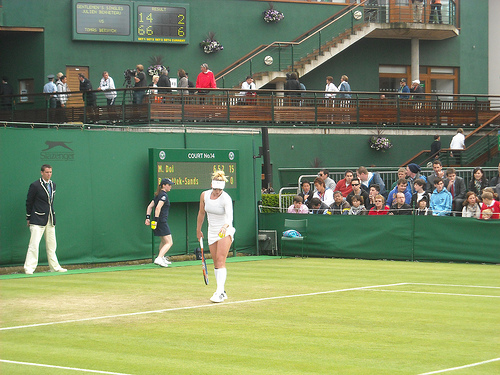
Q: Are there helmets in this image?
A: No, there are no helmets.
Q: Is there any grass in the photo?
A: Yes, there is grass.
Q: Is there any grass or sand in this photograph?
A: Yes, there is grass.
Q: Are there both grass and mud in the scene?
A: No, there is grass but no mud.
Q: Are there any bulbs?
A: No, there are no bulbs.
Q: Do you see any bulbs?
A: No, there are no bulbs.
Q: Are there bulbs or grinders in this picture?
A: No, there are no bulbs or grinders.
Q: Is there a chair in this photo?
A: No, there are no chairs.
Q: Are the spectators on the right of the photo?
A: Yes, the spectators are on the right of the image.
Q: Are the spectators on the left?
A: No, the spectators are on the right of the image.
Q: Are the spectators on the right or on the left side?
A: The spectators are on the right of the image.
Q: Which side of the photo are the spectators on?
A: The spectators are on the right of the image.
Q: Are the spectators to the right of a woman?
A: Yes, the spectators are to the right of a woman.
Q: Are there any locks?
A: No, there are no locks.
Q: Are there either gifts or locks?
A: No, there are no locks or gifts.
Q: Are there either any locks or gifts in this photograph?
A: No, there are no locks or gifts.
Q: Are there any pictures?
A: No, there are no pictures.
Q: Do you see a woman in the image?
A: Yes, there is a woman.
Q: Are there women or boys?
A: Yes, there is a woman.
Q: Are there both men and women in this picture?
A: Yes, there are both a woman and a man.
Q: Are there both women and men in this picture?
A: Yes, there are both a woman and a man.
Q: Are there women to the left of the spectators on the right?
A: Yes, there is a woman to the left of the spectators.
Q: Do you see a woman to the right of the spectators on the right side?
A: No, the woman is to the left of the spectators.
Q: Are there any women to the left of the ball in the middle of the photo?
A: Yes, there is a woman to the left of the ball.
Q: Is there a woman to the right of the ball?
A: No, the woman is to the left of the ball.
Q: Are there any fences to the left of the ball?
A: No, there is a woman to the left of the ball.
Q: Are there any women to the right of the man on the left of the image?
A: Yes, there is a woman to the right of the man.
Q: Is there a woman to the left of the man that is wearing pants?
A: No, the woman is to the right of the man.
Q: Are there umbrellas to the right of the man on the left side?
A: No, there is a woman to the right of the man.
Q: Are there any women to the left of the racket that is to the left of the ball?
A: Yes, there is a woman to the left of the racket.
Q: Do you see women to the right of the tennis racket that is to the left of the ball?
A: No, the woman is to the left of the racket.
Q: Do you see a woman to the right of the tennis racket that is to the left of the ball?
A: No, the woman is to the left of the racket.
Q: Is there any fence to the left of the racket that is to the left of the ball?
A: No, there is a woman to the left of the racket.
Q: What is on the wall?
A: The logo is on the wall.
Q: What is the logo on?
A: The logo is on the wall.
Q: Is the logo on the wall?
A: Yes, the logo is on the wall.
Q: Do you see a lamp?
A: No, there are no lamps.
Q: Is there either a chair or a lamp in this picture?
A: No, there are no lamps or chairs.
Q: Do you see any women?
A: Yes, there is a woman.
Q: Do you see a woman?
A: Yes, there is a woman.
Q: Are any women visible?
A: Yes, there is a woman.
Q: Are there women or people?
A: Yes, there is a woman.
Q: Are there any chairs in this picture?
A: No, there are no chairs.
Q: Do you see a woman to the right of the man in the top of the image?
A: Yes, there is a woman to the right of the man.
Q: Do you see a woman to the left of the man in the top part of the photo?
A: No, the woman is to the right of the man.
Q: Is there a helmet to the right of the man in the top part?
A: No, there is a woman to the right of the man.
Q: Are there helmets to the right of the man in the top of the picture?
A: No, there is a woman to the right of the man.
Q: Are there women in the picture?
A: Yes, there is a woman.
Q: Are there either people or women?
A: Yes, there is a woman.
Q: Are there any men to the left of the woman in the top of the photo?
A: Yes, there is a man to the left of the woman.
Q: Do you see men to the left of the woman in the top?
A: Yes, there is a man to the left of the woman.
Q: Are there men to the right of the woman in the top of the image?
A: No, the man is to the left of the woman.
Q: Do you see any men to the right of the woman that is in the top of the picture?
A: No, the man is to the left of the woman.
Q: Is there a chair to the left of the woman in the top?
A: No, there is a man to the left of the woman.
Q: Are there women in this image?
A: Yes, there is a woman.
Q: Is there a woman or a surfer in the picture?
A: Yes, there is a woman.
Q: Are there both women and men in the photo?
A: Yes, there are both a woman and a man.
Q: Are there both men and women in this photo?
A: Yes, there are both a woman and a man.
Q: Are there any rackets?
A: Yes, there is a racket.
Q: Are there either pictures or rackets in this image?
A: Yes, there is a racket.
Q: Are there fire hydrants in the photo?
A: No, there are no fire hydrants.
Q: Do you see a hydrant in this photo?
A: No, there are no fire hydrants.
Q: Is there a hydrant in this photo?
A: No, there are no fire hydrants.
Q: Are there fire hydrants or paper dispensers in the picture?
A: No, there are no fire hydrants or paper dispensers.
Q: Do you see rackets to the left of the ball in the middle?
A: Yes, there is a racket to the left of the ball.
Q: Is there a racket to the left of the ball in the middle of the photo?
A: Yes, there is a racket to the left of the ball.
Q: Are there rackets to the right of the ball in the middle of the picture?
A: No, the racket is to the left of the ball.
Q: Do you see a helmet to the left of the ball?
A: No, there is a racket to the left of the ball.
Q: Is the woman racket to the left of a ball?
A: Yes, the tennis racket is to the left of a ball.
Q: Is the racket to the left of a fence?
A: No, the racket is to the left of a ball.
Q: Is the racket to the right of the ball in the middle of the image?
A: No, the racket is to the left of the ball.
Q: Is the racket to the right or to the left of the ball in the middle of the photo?
A: The racket is to the left of the ball.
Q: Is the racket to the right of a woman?
A: Yes, the racket is to the right of a woman.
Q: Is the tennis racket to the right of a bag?
A: No, the tennis racket is to the right of a woman.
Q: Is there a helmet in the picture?
A: No, there are no helmets.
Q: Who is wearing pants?
A: The man is wearing pants.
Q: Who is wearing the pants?
A: The man is wearing pants.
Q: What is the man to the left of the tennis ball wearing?
A: The man is wearing pants.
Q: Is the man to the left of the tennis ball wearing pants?
A: Yes, the man is wearing pants.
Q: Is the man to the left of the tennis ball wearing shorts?
A: No, the man is wearing pants.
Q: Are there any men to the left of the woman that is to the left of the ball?
A: Yes, there is a man to the left of the woman.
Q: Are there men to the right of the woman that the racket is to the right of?
A: No, the man is to the left of the woman.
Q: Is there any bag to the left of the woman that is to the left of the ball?
A: No, there is a man to the left of the woman.